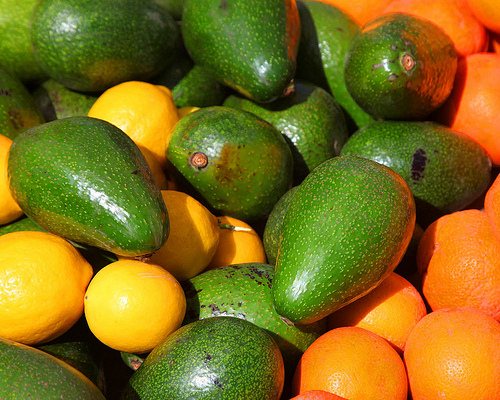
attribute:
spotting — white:
[436, 319, 451, 340]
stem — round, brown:
[187, 149, 212, 176]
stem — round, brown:
[394, 44, 418, 74]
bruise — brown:
[183, 144, 244, 184]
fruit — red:
[82, 257, 186, 352]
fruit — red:
[87, 79, 176, 169]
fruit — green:
[180, 0, 297, 104]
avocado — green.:
[266, 160, 411, 325]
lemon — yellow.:
[0, 230, 94, 345]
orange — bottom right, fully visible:
[277, 322, 410, 398]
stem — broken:
[218, 216, 255, 238]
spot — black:
[389, 141, 484, 213]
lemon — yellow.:
[81, 254, 189, 379]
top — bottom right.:
[279, 387, 332, 399]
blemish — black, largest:
[412, 145, 427, 183]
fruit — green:
[338, 111, 498, 230]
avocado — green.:
[163, 101, 300, 226]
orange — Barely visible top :
[323, 380, 351, 398]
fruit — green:
[342, 10, 462, 120]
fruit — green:
[7, 113, 171, 258]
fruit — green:
[269, 151, 419, 329]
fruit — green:
[162, 102, 293, 223]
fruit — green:
[340, 119, 484, 212]